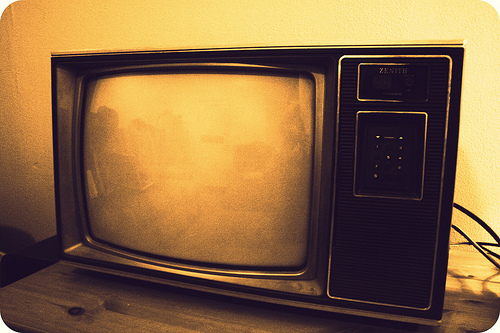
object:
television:
[47, 38, 470, 331]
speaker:
[329, 198, 432, 311]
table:
[2, 249, 499, 333]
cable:
[448, 202, 500, 269]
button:
[374, 133, 380, 151]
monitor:
[66, 61, 322, 275]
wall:
[0, 2, 497, 264]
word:
[376, 67, 409, 74]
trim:
[323, 50, 455, 314]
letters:
[377, 66, 385, 74]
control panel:
[353, 109, 428, 200]